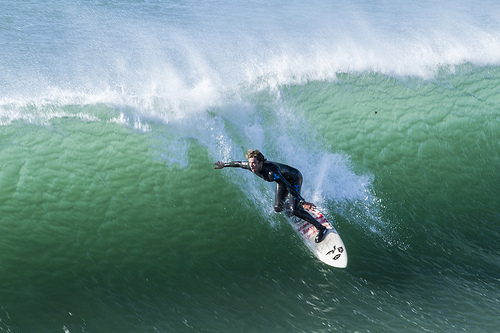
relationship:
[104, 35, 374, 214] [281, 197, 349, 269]
spraying water in surfboard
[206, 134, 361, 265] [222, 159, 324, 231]
surfer has wet suit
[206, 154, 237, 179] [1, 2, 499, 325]
surfers hand touching water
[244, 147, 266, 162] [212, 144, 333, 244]
hair of man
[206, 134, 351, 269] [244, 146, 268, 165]
surfer has hair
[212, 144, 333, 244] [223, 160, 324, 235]
man wears wetsuit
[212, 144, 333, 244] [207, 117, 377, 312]
man on top of surfboard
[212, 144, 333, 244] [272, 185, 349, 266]
man riding surfboard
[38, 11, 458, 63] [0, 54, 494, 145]
spray from top of wave crest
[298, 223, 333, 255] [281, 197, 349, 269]
foot on surfboard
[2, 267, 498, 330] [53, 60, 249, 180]
water in front of wave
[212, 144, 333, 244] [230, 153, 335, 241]
man wearing a wetsuit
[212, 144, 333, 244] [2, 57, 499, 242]
man surfing on wave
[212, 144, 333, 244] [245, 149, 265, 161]
man with hair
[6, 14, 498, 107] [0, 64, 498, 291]
sea spray on wave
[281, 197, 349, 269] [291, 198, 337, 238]
surfboard with stripes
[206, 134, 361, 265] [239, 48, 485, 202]
surfer riding wave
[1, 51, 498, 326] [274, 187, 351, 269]
water from surfboard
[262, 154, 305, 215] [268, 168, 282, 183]
wet suit with logo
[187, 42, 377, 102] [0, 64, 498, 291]
splash from wave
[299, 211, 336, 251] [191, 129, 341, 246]
surfing boots on surfter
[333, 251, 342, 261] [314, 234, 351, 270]
black sticker on surfboard